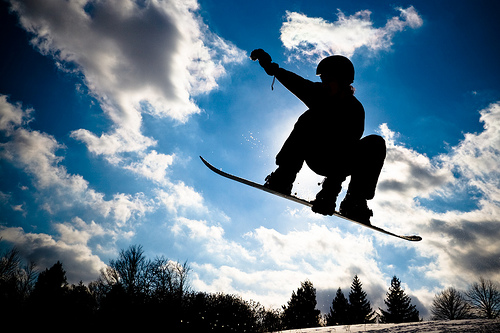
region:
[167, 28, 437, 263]
snowboarder in the air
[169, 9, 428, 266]
snowboarder in the air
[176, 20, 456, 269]
snowboarder in the air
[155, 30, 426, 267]
snowboarder in the air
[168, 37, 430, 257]
snowboarder in the air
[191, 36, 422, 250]
snowboarder in the air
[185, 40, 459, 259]
snowboarder in the air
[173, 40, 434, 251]
snowboarder in the air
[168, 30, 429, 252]
snowboarder in the air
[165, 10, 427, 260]
snowboarder in the air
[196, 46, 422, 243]
Person is on snowboard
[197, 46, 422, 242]
Person is wearing a helmet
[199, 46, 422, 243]
Person has on gloves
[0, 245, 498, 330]
Trees are behind snowboarder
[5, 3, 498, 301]
Clouds are above the snowboarder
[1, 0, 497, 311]
The sky is above the clouds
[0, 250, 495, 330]
The trees are under the clouds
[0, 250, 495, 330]
Trees are under the sky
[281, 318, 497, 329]
The ground is under the snowboarder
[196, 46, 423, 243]
Snowboarder is over the ground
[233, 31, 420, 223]
person is on snowboard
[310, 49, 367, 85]
person is wearing helmet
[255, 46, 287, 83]
person is wearing gloves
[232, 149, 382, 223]
person is wearing boots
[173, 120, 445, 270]
snowboard is in air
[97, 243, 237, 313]
bare trees in distance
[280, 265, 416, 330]
group of pine trees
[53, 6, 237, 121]
grey and thick clouds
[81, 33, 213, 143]
Section of the clouds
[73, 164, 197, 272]
Section of the clouds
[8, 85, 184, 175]
Section of the clouds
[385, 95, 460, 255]
Section of the clouds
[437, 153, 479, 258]
Section of the clouds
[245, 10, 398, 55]
Section of the clouds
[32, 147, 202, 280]
Section of the clouds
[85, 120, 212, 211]
Section of the clouds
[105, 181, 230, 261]
Section of the clouds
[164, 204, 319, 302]
Section of the clouds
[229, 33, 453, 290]
This is a person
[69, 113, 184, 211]
Section of the clouds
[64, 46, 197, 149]
Section of the clouds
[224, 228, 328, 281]
Section of the clouds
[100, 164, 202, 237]
Section of the clouds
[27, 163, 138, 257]
Section of the clouds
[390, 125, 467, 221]
Section of the clouds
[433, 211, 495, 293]
Section of the clouds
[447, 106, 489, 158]
Section of the clouds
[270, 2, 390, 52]
Section of the clouds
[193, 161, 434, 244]
board under the person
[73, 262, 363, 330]
trees in the distance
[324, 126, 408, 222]
leg of the person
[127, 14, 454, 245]
person wearing a helmet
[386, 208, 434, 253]
back of the board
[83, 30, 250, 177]
white and blue sky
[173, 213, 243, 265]
white cloud in blue sky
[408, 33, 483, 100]
blue sky above the land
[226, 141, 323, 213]
foot of the person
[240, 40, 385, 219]
person jumping on the snowboard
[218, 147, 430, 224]
wooden dark snowbooard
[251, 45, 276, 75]
dark glove in right hand